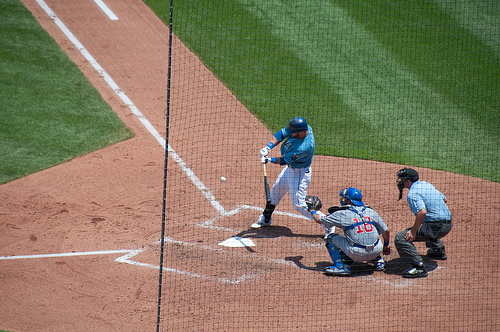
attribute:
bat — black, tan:
[256, 150, 277, 214]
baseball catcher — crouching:
[307, 179, 383, 317]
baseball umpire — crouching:
[388, 158, 458, 288]